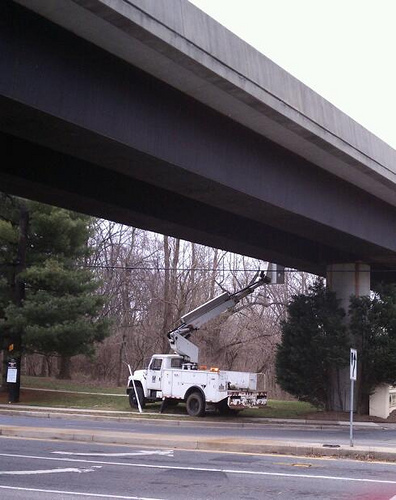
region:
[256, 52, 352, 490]
concrete overpass over road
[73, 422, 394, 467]
concrete median in road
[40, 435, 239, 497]
white turn arrows on road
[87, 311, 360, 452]
work truck parked on grass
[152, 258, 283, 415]
lift on truck raised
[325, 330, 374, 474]
road divider sign in roadway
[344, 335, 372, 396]
black and white sign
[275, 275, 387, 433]
trees growing around concrete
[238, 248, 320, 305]
bucket of truck near overpass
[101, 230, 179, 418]
bare trees behind truck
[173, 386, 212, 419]
tire on the car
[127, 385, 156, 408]
front tire of the truck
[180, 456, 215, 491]
line on the street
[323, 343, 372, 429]
sign on the street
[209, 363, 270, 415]
back of the truck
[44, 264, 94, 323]
tree next to the street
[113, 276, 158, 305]
branches of the trees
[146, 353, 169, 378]
window on the truck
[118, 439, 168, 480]
white turn arrow on street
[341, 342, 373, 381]
black arrow pointing up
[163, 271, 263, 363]
The lift for the truck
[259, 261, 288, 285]
the cage atop the lift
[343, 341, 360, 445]
a white street sign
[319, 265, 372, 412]
a column for the bridge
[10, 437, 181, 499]
white arrows on the ground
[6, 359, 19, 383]
a sign on the post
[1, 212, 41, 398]
post for the power lines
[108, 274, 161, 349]
bare trees behind the truck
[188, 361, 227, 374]
orange lights on the truck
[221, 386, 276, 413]
rust on the back of the truck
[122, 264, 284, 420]
a white cherry picker vehicle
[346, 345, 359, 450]
a traffic direction sign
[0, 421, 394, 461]
a raised street median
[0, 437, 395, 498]
a paved city street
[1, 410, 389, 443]
a paved city street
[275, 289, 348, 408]
a short green tree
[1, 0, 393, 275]
a traffic overpass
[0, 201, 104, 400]
a large evergreen tree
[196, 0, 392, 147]
a cloudy white sky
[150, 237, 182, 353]
a bare brown tree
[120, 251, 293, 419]
white truck with bucket lift parked under highway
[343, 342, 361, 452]
white and black rectangular traffic sign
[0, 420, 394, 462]
long concrete island dividing the road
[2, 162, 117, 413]
green evergreen tree next to road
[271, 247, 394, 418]
large green bush next to road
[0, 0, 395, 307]
gray concrete highway overpass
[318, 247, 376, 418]
light gray concrete support pillar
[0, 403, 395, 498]
light gray concrete road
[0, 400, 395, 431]
light gray concrete sidewalk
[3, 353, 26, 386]
white sign posted on tree